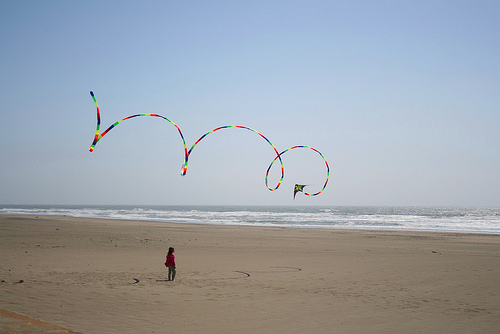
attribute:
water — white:
[2, 192, 498, 237]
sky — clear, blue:
[0, 1, 499, 205]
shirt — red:
[160, 241, 187, 268]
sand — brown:
[312, 235, 483, 314]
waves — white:
[134, 191, 499, 233]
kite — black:
[75, 85, 333, 201]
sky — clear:
[2, 0, 489, 232]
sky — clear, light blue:
[290, 33, 379, 102]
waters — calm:
[193, 204, 495, 211]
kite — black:
[289, 177, 309, 202]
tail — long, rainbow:
[84, 90, 331, 199]